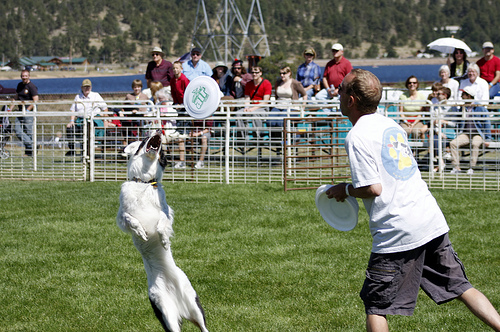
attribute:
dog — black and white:
[114, 129, 211, 329]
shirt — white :
[343, 112, 450, 254]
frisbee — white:
[183, 70, 225, 120]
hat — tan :
[75, 75, 93, 91]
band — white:
[345, 181, 351, 196]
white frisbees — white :
[309, 177, 361, 231]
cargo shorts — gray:
[360, 234, 473, 312]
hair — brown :
[342, 64, 391, 114]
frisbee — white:
[166, 68, 221, 117]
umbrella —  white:
[427, 37, 473, 57]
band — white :
[344, 181, 351, 195]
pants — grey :
[360, 230, 472, 315]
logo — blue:
[190, 85, 208, 108]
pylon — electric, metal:
[186, 0, 273, 64]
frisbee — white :
[167, 71, 220, 122]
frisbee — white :
[184, 75, 221, 117]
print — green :
[192, 85, 206, 108]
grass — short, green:
[2, 177, 499, 329]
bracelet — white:
[341, 180, 353, 205]